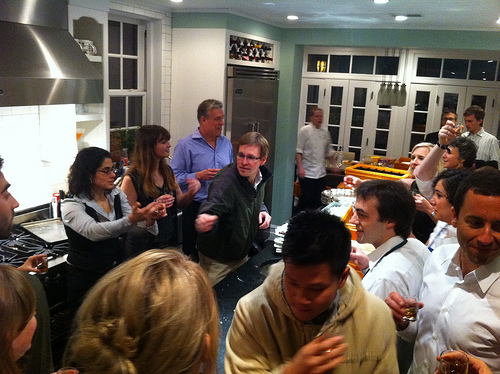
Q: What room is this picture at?
A: It is at the kitchen.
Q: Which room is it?
A: It is a kitchen.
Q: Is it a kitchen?
A: Yes, it is a kitchen.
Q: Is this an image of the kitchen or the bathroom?
A: It is showing the kitchen.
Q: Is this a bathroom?
A: No, it is a kitchen.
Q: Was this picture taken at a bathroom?
A: No, the picture was taken in a kitchen.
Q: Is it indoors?
A: Yes, it is indoors.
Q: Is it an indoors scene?
A: Yes, it is indoors.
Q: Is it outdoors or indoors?
A: It is indoors.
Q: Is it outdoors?
A: No, it is indoors.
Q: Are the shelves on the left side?
A: Yes, the shelves are on the left of the image.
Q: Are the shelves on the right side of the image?
A: No, the shelves are on the left of the image.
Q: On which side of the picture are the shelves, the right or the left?
A: The shelves are on the left of the image.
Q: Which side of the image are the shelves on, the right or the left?
A: The shelves are on the left of the image.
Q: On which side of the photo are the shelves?
A: The shelves are on the left of the image.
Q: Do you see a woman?
A: Yes, there is a woman.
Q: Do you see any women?
A: Yes, there is a woman.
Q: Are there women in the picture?
A: Yes, there is a woman.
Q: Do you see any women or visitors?
A: Yes, there is a woman.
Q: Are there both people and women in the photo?
A: Yes, there are both a woman and a person.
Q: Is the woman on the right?
A: Yes, the woman is on the right of the image.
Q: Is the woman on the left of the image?
A: No, the woman is on the right of the image.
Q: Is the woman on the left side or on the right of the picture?
A: The woman is on the right of the image.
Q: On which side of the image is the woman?
A: The woman is on the right of the image.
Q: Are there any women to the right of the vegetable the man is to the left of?
A: Yes, there is a woman to the right of the vegetable.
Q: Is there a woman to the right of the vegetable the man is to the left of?
A: Yes, there is a woman to the right of the vegetable.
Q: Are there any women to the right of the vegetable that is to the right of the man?
A: Yes, there is a woman to the right of the vegetable.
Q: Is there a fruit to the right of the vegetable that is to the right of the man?
A: No, there is a woman to the right of the vegetable.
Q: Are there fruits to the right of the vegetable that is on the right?
A: No, there is a woman to the right of the vegetable.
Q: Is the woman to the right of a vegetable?
A: Yes, the woman is to the right of a vegetable.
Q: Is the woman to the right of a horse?
A: No, the woman is to the right of a vegetable.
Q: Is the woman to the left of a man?
A: No, the woman is to the right of a man.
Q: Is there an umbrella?
A: No, there are no umbrellas.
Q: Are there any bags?
A: No, there are no bags.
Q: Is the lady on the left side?
A: Yes, the lady is on the left of the image.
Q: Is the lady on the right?
A: No, the lady is on the left of the image.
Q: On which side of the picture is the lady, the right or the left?
A: The lady is on the left of the image.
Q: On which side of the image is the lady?
A: The lady is on the left of the image.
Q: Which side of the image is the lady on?
A: The lady is on the left of the image.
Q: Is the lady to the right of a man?
A: No, the lady is to the left of a man.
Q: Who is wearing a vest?
A: The lady is wearing a vest.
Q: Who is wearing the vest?
A: The lady is wearing a vest.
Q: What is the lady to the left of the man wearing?
A: The lady is wearing a vest.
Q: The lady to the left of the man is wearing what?
A: The lady is wearing a vest.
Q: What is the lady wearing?
A: The lady is wearing a vest.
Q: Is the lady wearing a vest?
A: Yes, the lady is wearing a vest.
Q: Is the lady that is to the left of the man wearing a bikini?
A: No, the lady is wearing a vest.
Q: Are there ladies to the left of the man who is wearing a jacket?
A: Yes, there is a lady to the left of the man.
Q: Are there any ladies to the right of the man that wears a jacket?
A: No, the lady is to the left of the man.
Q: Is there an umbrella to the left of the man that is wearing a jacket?
A: No, there is a lady to the left of the man.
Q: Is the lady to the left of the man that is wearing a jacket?
A: Yes, the lady is to the left of the man.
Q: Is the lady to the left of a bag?
A: No, the lady is to the left of the man.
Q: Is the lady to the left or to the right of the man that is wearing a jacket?
A: The lady is to the left of the man.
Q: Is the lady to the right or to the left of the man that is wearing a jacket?
A: The lady is to the left of the man.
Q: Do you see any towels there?
A: No, there are no towels.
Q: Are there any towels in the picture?
A: No, there are no towels.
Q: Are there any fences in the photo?
A: No, there are no fences.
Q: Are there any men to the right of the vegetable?
A: Yes, there is a man to the right of the vegetable.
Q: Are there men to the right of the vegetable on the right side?
A: Yes, there is a man to the right of the vegetable.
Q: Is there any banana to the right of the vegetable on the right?
A: No, there is a man to the right of the vegetable.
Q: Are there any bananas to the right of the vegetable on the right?
A: No, there is a man to the right of the vegetable.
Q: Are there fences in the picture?
A: No, there are no fences.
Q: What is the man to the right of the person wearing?
A: The man is wearing a shirt.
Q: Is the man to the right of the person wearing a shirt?
A: Yes, the man is wearing a shirt.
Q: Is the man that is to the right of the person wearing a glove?
A: No, the man is wearing a shirt.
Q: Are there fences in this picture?
A: No, there are no fences.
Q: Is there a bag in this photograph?
A: No, there are no bags.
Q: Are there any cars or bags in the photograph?
A: No, there are no bags or cars.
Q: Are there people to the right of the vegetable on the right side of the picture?
A: Yes, there is a person to the right of the vegetable.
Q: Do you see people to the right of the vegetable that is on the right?
A: Yes, there is a person to the right of the vegetable.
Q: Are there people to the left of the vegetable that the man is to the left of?
A: No, the person is to the right of the vegetable.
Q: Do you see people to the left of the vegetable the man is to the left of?
A: No, the person is to the right of the vegetable.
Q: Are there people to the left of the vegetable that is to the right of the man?
A: No, the person is to the right of the vegetable.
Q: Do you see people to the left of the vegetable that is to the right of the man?
A: No, the person is to the right of the vegetable.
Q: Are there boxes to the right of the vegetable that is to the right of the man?
A: No, there is a person to the right of the vegetable.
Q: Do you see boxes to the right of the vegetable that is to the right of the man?
A: No, there is a person to the right of the vegetable.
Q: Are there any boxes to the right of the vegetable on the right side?
A: No, there is a person to the right of the vegetable.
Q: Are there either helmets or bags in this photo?
A: No, there are no bags or helmets.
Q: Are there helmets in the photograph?
A: No, there are no helmets.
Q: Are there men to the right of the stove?
A: Yes, there is a man to the right of the stove.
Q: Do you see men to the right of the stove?
A: Yes, there is a man to the right of the stove.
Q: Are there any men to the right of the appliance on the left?
A: Yes, there is a man to the right of the stove.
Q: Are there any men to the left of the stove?
A: No, the man is to the right of the stove.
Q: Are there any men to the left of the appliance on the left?
A: No, the man is to the right of the stove.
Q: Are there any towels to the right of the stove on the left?
A: No, there is a man to the right of the stove.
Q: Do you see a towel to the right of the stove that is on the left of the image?
A: No, there is a man to the right of the stove.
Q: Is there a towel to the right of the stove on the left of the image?
A: No, there is a man to the right of the stove.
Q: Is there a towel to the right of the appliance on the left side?
A: No, there is a man to the right of the stove.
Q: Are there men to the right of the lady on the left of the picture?
A: Yes, there is a man to the right of the lady.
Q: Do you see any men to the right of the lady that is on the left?
A: Yes, there is a man to the right of the lady.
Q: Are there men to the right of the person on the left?
A: Yes, there is a man to the right of the lady.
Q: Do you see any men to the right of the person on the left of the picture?
A: Yes, there is a man to the right of the lady.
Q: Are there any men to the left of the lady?
A: No, the man is to the right of the lady.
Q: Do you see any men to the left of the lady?
A: No, the man is to the right of the lady.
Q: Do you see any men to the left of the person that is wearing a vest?
A: No, the man is to the right of the lady.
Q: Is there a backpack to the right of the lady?
A: No, there is a man to the right of the lady.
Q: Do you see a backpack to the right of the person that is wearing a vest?
A: No, there is a man to the right of the lady.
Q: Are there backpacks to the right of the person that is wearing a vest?
A: No, there is a man to the right of the lady.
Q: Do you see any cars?
A: No, there are no cars.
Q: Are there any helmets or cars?
A: No, there are no cars or helmets.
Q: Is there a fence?
A: No, there are no fences.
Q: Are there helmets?
A: No, there are no helmets.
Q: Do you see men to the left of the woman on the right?
A: Yes, there is a man to the left of the woman.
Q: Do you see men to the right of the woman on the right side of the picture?
A: No, the man is to the left of the woman.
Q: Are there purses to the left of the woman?
A: No, there is a man to the left of the woman.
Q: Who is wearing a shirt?
A: The man is wearing a shirt.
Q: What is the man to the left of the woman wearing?
A: The man is wearing a shirt.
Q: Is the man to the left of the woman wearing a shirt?
A: Yes, the man is wearing a shirt.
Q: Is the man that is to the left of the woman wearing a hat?
A: No, the man is wearing a shirt.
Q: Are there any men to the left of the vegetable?
A: Yes, there is a man to the left of the vegetable.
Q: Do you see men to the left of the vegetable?
A: Yes, there is a man to the left of the vegetable.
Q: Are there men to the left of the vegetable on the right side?
A: Yes, there is a man to the left of the vegetable.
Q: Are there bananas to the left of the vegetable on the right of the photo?
A: No, there is a man to the left of the vegetable.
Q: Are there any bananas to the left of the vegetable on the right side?
A: No, there is a man to the left of the vegetable.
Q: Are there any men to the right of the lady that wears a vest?
A: Yes, there is a man to the right of the lady.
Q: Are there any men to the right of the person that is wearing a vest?
A: Yes, there is a man to the right of the lady.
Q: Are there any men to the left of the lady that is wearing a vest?
A: No, the man is to the right of the lady.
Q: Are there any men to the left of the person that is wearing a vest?
A: No, the man is to the right of the lady.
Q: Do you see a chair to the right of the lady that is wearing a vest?
A: No, there is a man to the right of the lady.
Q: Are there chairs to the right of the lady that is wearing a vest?
A: No, there is a man to the right of the lady.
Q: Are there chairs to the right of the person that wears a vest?
A: No, there is a man to the right of the lady.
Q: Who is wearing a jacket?
A: The man is wearing a jacket.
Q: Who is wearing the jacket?
A: The man is wearing a jacket.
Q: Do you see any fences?
A: No, there are no fences.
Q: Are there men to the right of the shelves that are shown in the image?
A: Yes, there is a man to the right of the shelves.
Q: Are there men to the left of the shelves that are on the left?
A: No, the man is to the right of the shelves.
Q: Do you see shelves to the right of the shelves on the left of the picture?
A: No, there is a man to the right of the shelves.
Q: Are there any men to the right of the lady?
A: Yes, there is a man to the right of the lady.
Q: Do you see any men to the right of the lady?
A: Yes, there is a man to the right of the lady.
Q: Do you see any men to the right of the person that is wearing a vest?
A: Yes, there is a man to the right of the lady.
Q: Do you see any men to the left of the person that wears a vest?
A: No, the man is to the right of the lady.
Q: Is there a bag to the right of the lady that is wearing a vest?
A: No, there is a man to the right of the lady.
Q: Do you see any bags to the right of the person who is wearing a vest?
A: No, there is a man to the right of the lady.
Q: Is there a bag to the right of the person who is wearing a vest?
A: No, there is a man to the right of the lady.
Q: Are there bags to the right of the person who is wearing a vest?
A: No, there is a man to the right of the lady.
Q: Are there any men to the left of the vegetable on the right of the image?
A: Yes, there is a man to the left of the vegetable.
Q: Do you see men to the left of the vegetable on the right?
A: Yes, there is a man to the left of the vegetable.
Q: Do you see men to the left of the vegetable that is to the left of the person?
A: Yes, there is a man to the left of the vegetable.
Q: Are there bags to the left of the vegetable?
A: No, there is a man to the left of the vegetable.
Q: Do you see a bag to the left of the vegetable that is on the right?
A: No, there is a man to the left of the vegetable.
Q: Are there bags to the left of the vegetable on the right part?
A: No, there is a man to the left of the vegetable.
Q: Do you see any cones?
A: No, there are no cones.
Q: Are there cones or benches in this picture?
A: No, there are no cones or benches.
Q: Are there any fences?
A: No, there are no fences.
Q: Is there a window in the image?
A: Yes, there is a window.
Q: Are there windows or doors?
A: Yes, there is a window.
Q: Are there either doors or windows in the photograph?
A: Yes, there is a window.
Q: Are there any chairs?
A: No, there are no chairs.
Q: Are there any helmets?
A: No, there are no helmets.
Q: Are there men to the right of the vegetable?
A: Yes, there is a man to the right of the vegetable.